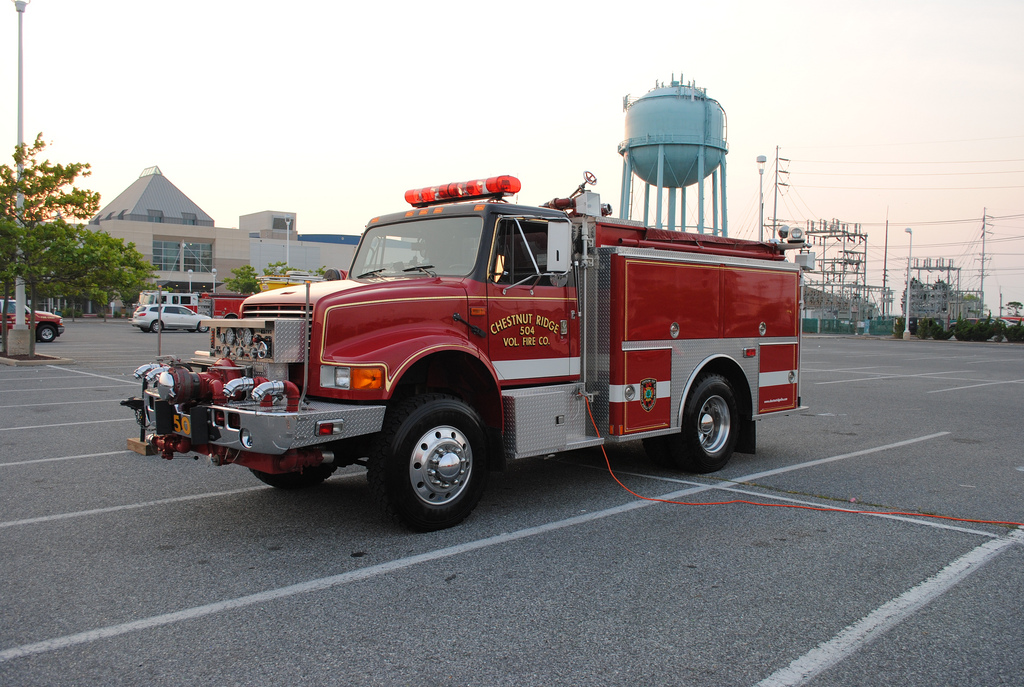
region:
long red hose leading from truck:
[568, 382, 1021, 582]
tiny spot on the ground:
[428, 561, 504, 585]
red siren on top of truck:
[392, 169, 539, 201]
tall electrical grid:
[809, 212, 980, 329]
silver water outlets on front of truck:
[218, 361, 313, 423]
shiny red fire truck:
[122, 125, 849, 474]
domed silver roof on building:
[106, 141, 227, 227]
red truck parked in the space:
[11, 286, 95, 345]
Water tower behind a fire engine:
[606, 58, 755, 469]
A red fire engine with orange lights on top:
[120, 176, 829, 543]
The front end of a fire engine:
[117, 271, 422, 497]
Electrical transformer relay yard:
[762, 151, 1013, 376]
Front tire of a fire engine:
[373, 379, 500, 551]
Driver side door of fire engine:
[480, 187, 611, 478]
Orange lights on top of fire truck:
[384, 168, 543, 235]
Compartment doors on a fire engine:
[588, 214, 814, 487]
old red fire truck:
[257, 162, 807, 486]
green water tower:
[585, 60, 763, 235]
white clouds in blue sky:
[277, 48, 323, 83]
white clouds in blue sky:
[298, 48, 379, 109]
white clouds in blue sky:
[845, 104, 929, 177]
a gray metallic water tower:
[614, 72, 732, 232]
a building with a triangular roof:
[86, 169, 359, 305]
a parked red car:
[0, 293, 64, 342]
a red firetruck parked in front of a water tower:
[122, 69, 806, 526]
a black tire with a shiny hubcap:
[364, 393, 485, 534]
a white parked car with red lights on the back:
[130, 299, 210, 337]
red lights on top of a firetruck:
[121, 172, 808, 528]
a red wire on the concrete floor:
[582, 401, 1019, 528]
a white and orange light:
[315, 361, 385, 396]